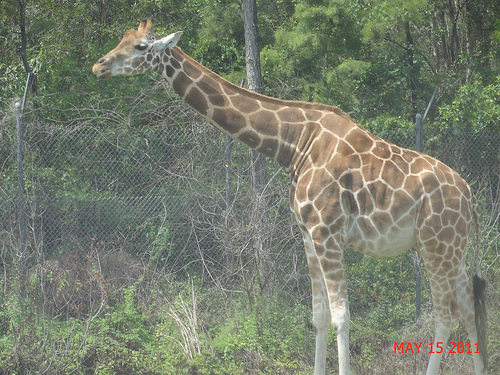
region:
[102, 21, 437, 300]
the giraffe is standing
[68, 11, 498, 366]
A giraffe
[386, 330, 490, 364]
date that the picture was taken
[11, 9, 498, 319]
fence on the right side of the giraffe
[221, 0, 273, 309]
a long tree trunk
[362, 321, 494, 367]
red letters and numbers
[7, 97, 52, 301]
a metal fence post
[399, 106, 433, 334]
metal fence post on the right side of a giraffe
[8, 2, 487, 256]
green trees behind the metal fence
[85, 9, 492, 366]
one giraffe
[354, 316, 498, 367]
the date printed in red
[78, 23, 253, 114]
the giraffe has ears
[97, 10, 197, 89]
the giraffe has ears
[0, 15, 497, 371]
A giraffe in daylight.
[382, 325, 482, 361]
The red text says May 15, 2011.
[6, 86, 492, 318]
A fence behind the giraffe.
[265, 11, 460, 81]
Green trees in the background.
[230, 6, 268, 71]
The trunk of the tree.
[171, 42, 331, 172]
The giraffe has a long neck.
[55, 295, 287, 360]
Small green plants on the ground.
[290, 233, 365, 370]
The giraffe has two front legs.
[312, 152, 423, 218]
The giraffe has brown spots.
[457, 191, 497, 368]
The giraffe has a tail.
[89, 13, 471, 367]
tall giraffe outside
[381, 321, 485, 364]
printed date in red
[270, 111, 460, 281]
stone like patterned designs on fur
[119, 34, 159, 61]
big black eyes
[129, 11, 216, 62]
long ears of a giraffe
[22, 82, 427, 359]
tall metal fence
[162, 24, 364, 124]
short brown mane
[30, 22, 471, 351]
dense area of trees and brush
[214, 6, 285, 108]
thin tree trunk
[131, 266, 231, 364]
brown dead brush near the fence